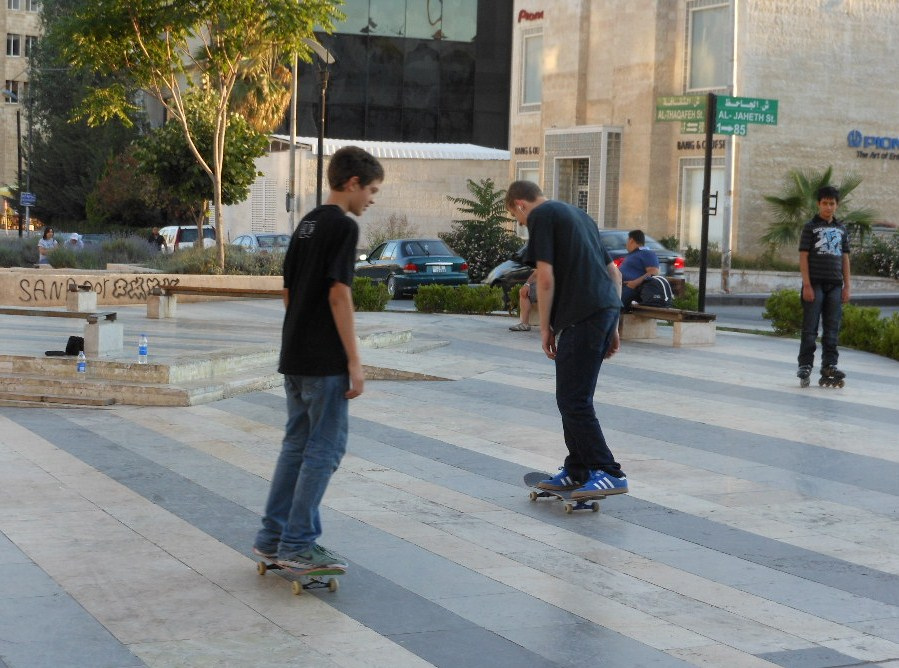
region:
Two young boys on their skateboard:
[251, 144, 635, 599]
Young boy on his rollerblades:
[793, 184, 854, 394]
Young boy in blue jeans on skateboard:
[247, 139, 388, 597]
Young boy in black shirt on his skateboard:
[248, 141, 387, 599]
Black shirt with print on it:
[795, 217, 855, 292]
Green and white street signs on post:
[644, 80, 782, 312]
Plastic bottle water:
[133, 324, 149, 358]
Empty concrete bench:
[3, 296, 127, 358]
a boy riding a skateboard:
[254, 126, 383, 596]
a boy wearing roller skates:
[784, 178, 852, 400]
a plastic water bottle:
[131, 318, 150, 370]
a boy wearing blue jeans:
[242, 368, 356, 551]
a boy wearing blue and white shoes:
[536, 463, 641, 504]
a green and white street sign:
[715, 88, 783, 138]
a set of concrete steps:
[134, 348, 243, 419]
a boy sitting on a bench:
[610, 201, 674, 324]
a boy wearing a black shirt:
[536, 204, 619, 324]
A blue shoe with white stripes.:
[572, 473, 627, 496]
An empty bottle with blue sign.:
[73, 349, 88, 383]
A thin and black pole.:
[695, 92, 719, 314]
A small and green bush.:
[411, 284, 502, 314]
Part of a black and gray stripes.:
[358, 570, 688, 666]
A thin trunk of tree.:
[175, 68, 236, 270]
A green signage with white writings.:
[715, 98, 776, 137]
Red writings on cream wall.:
[514, 8, 547, 24]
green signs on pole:
[658, 93, 778, 307]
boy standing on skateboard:
[250, 147, 382, 596]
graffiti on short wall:
[1, 271, 280, 303]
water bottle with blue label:
[135, 333, 150, 366]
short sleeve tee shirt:
[527, 202, 619, 327]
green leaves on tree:
[69, 0, 336, 272]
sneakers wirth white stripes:
[538, 468, 626, 500]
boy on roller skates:
[795, 188, 846, 389]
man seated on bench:
[620, 229, 715, 345]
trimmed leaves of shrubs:
[349, 283, 506, 306]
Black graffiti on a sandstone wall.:
[14, 266, 188, 312]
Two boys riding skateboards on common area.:
[252, 117, 638, 605]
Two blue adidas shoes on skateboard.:
[507, 451, 639, 521]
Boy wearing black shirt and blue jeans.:
[255, 126, 385, 571]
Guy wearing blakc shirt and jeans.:
[491, 179, 646, 474]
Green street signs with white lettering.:
[654, 83, 793, 148]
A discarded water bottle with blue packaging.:
[62, 345, 100, 379]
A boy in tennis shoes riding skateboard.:
[252, 140, 386, 601]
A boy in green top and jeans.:
[790, 183, 867, 393]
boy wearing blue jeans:
[247, 354, 354, 558]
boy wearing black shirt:
[267, 192, 371, 392]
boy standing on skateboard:
[244, 529, 349, 600]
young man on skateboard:
[494, 174, 642, 504]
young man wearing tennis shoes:
[537, 455, 633, 508]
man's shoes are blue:
[535, 451, 633, 513]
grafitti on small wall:
[5, 266, 193, 316]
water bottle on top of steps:
[131, 328, 152, 363]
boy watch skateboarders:
[792, 176, 848, 396]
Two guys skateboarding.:
[221, 144, 667, 588]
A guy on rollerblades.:
[787, 191, 871, 384]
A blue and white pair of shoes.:
[528, 461, 628, 500]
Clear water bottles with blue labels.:
[70, 334, 163, 380]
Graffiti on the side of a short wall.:
[22, 268, 182, 315]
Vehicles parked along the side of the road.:
[44, 209, 700, 291]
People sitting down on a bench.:
[530, 221, 687, 337]